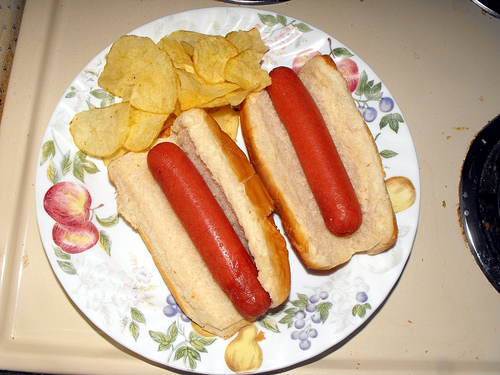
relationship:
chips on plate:
[69, 26, 271, 167] [34, 8, 421, 373]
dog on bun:
[265, 62, 364, 237] [239, 53, 400, 274]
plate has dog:
[34, 8, 421, 373] [265, 62, 364, 237]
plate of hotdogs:
[34, 8, 421, 373] [105, 107, 293, 341]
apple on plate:
[40, 181, 105, 230] [34, 8, 421, 373]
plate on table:
[34, 8, 421, 373] [2, 0, 497, 370]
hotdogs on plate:
[109, 54, 402, 337] [34, 8, 421, 373]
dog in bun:
[265, 62, 364, 237] [239, 53, 400, 274]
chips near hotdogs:
[69, 26, 271, 167] [109, 54, 402, 337]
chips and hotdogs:
[69, 26, 271, 167] [109, 54, 402, 337]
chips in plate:
[69, 26, 271, 167] [34, 8, 421, 373]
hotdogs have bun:
[109, 54, 402, 337] [239, 53, 400, 274]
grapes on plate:
[286, 287, 330, 351] [34, 8, 421, 373]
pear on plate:
[221, 327, 274, 374] [34, 8, 421, 373]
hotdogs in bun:
[109, 54, 402, 337] [239, 53, 400, 274]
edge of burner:
[461, 161, 480, 237] [466, 104, 500, 297]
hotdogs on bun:
[109, 54, 402, 337] [239, 53, 400, 274]